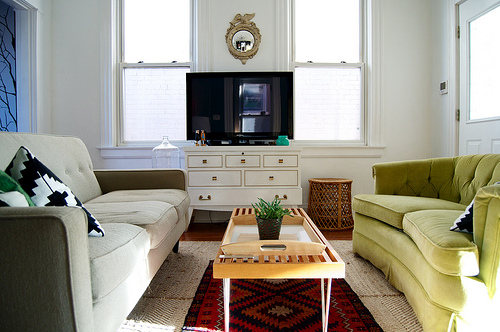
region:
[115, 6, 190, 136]
window on the wall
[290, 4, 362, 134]
window on the wall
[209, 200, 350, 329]
table on the rug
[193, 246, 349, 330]
rug in center of room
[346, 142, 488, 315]
couch near the door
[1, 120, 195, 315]
couch against the wall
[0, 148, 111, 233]
pillows on the couch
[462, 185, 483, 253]
pillow on the couch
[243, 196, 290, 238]
plant on the table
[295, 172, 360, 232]
basket on the floor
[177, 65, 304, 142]
the television on the dresser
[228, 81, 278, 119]
the reflection on the screen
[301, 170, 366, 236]
basket beside the dresser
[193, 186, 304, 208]
the large drawer of the dresser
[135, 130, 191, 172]
jug beside the dresser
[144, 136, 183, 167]
the jug is glass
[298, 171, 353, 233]
the basket is straw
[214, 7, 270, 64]
the mirror on the wall above the television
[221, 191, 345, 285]
tray on the coffee table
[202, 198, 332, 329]
the coffee table is wooden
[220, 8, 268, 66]
the mirror on the wall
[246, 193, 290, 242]
the small plant on the coffee table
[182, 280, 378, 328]
the red rug under the table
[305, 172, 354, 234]
the wicker stand by the dresser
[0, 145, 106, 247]
the throw pillows on the couch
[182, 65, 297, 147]
the black flat screen tv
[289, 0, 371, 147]
the window behind the TV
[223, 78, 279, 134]
the reflection on the screen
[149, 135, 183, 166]
the top of the white birdcage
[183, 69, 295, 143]
a flat screen television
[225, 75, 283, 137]
a reflection in the flat screen television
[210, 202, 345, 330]
a small wooden coffee table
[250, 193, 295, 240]
a small potted plant on the coffee table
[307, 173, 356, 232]
a wicker stool next to the window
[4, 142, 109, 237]
a decorative pillow on the couch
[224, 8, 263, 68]
a small gold mirror on the wall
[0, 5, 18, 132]
tree branches seen from the window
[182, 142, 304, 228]
a white chest of drawers with a TV on top of it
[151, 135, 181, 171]
a large plastic jug next to the chest of drawers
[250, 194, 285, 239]
Potted plant on a tray on the table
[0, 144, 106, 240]
Pillows on the sofa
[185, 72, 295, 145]
Television on the dresser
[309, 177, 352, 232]
Small wicker table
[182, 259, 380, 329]
Area rug under the coffee table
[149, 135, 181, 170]
Glass jug in front of the window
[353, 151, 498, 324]
Green sofa to the right of the coffee table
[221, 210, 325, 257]
Wooden tray on top of the coffee table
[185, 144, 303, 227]
White dresser between the two windows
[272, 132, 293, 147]
Small jar on the dresser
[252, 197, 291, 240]
Green plant in a brown basket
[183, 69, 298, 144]
A black flat screen TV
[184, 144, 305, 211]
A white cabinet with gold handles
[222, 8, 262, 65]
A gold mirror with a bird on top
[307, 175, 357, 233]
A brown wicker basket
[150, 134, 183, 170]
A clear glass jug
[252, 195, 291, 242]
A aloe vera plant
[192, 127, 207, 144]
Two standing people figurines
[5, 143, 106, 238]
A black and white throw pillow